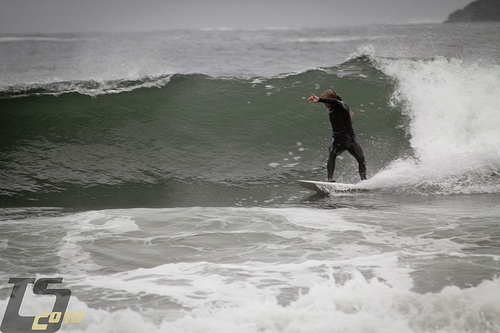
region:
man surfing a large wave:
[260, 56, 415, 211]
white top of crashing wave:
[76, 235, 471, 325]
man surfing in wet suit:
[285, 77, 400, 212]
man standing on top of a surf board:
[242, 66, 407, 221]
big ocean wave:
[6, 48, 496, 243]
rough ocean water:
[15, 60, 452, 296]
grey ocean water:
[25, 127, 291, 307]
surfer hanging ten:
[212, 56, 447, 207]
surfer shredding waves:
[266, 68, 446, 241]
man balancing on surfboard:
[268, 55, 405, 229]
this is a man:
[303, 81, 364, 198]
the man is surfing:
[300, 76, 369, 201]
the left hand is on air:
[311, 94, 332, 109]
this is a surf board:
[299, 172, 369, 205]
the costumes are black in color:
[328, 100, 353, 153]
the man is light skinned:
[308, 93, 316, 102]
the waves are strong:
[388, 61, 486, 197]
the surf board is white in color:
[299, 174, 341, 200]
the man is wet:
[321, 86, 356, 183]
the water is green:
[17, 73, 289, 225]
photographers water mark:
[11, 246, 113, 330]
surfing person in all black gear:
[173, 28, 457, 217]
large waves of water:
[45, 24, 486, 230]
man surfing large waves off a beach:
[33, 1, 495, 230]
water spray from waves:
[323, 33, 473, 210]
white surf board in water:
[295, 166, 419, 216]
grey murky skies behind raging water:
[19, 2, 491, 54]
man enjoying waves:
[269, 35, 431, 237]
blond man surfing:
[265, 50, 418, 222]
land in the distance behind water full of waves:
[337, 3, 493, 42]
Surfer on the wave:
[273, 61, 423, 221]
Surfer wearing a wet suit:
[303, 70, 399, 214]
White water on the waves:
[286, 57, 497, 194]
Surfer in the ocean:
[228, 50, 468, 282]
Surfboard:
[159, 43, 457, 195]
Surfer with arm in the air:
[273, 65, 451, 260]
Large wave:
[168, 60, 475, 193]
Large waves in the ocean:
[208, 49, 487, 282]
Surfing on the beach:
[211, 56, 493, 227]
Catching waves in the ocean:
[108, 71, 470, 207]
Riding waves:
[298, 49, 373, 271]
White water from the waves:
[325, 90, 455, 162]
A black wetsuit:
[282, 72, 430, 302]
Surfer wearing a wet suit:
[284, 35, 429, 262]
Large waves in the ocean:
[91, 37, 330, 199]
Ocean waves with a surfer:
[121, 48, 478, 300]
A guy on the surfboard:
[234, 27, 436, 304]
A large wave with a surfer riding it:
[198, 49, 372, 267]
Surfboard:
[260, 53, 450, 294]